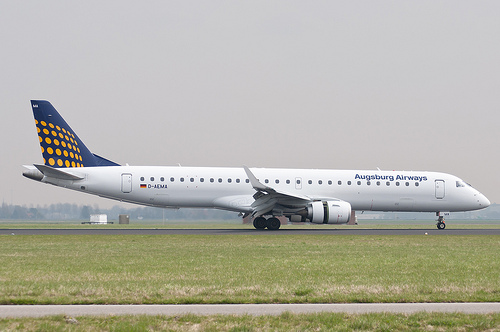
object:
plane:
[22, 99, 491, 230]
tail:
[22, 100, 120, 189]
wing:
[213, 164, 312, 219]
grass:
[0, 221, 500, 332]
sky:
[1, 0, 496, 219]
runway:
[0, 228, 500, 235]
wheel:
[437, 223, 445, 229]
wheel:
[266, 218, 280, 230]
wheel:
[253, 216, 267, 229]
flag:
[140, 184, 147, 188]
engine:
[305, 200, 352, 224]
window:
[150, 177, 154, 181]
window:
[180, 178, 184, 182]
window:
[236, 179, 240, 183]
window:
[286, 180, 290, 184]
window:
[367, 181, 371, 185]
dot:
[48, 158, 55, 166]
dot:
[45, 137, 51, 144]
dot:
[65, 160, 70, 168]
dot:
[54, 139, 60, 146]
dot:
[73, 145, 77, 151]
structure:
[81, 214, 113, 224]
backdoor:
[122, 174, 132, 193]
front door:
[435, 180, 444, 198]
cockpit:
[456, 181, 471, 187]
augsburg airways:
[355, 174, 428, 182]